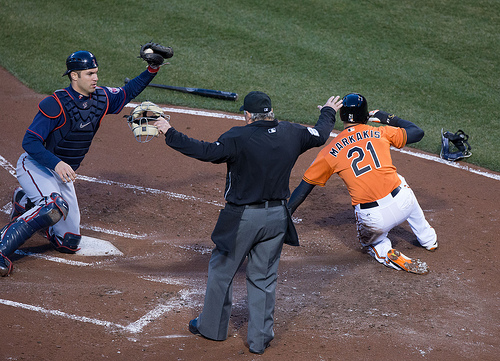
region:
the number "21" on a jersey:
[342, 142, 387, 182]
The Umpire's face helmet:
[128, 98, 170, 140]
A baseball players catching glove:
[127, 41, 181, 66]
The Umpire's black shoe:
[184, 308, 211, 337]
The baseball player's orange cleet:
[384, 250, 433, 278]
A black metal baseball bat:
[151, 80, 240, 103]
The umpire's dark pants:
[195, 201, 287, 343]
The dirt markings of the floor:
[30, 259, 177, 349]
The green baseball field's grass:
[0, 0, 497, 34]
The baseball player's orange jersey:
[322, 126, 400, 198]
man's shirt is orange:
[322, 109, 411, 196]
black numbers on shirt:
[333, 131, 387, 185]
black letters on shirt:
[305, 121, 401, 168]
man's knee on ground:
[337, 227, 427, 279]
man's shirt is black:
[206, 124, 292, 200]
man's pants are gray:
[175, 194, 297, 353]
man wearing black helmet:
[335, 72, 370, 130]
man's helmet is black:
[46, 27, 109, 72]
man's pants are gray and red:
[9, 144, 107, 251]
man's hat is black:
[224, 79, 292, 126]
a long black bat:
[125, 74, 245, 103]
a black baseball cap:
[232, 90, 277, 113]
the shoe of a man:
[388, 248, 432, 275]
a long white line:
[397, 145, 498, 188]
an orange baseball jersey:
[305, 125, 405, 199]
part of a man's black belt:
[358, 182, 404, 211]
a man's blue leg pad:
[1, 205, 61, 261]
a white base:
[76, 231, 124, 258]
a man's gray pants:
[197, 202, 288, 350]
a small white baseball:
[142, 44, 153, 54]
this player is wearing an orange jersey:
[311, 84, 453, 301]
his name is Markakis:
[317, 61, 434, 280]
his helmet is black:
[335, 85, 371, 143]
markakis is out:
[66, 39, 458, 359]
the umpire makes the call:
[161, 88, 357, 357]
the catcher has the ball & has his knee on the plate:
[7, 50, 125, 280]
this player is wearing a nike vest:
[0, 43, 180, 270]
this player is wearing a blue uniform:
[23, 54, 110, 254]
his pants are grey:
[8, 156, 112, 293]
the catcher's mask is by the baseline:
[436, 126, 491, 168]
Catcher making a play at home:
[0, 41, 170, 276]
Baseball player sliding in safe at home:
[285, 93, 440, 274]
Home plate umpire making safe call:
[151, 90, 343, 352]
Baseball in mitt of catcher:
[135, 40, 156, 63]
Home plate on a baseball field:
[62, 230, 122, 260]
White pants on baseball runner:
[350, 178, 437, 268]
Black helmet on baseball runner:
[338, 90, 369, 127]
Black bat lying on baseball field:
[127, 73, 239, 101]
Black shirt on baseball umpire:
[160, 105, 335, 206]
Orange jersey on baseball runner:
[300, 122, 410, 207]